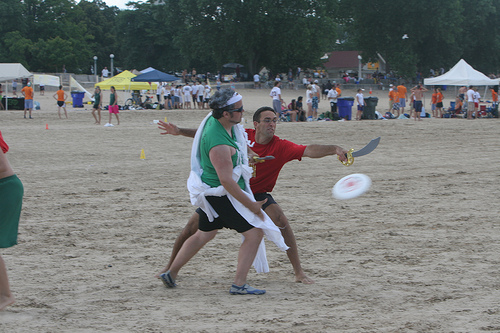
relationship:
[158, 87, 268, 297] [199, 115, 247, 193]
man in shirt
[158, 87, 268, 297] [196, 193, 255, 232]
man in shorts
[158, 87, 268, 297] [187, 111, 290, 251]
man wrapped in toilet paper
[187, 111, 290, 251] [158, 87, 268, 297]
toilet paper around man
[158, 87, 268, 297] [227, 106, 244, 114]
man wearing glasses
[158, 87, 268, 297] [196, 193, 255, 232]
man wearing shorts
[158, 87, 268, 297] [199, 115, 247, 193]
man wearing shirt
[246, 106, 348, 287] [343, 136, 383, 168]
man holding knife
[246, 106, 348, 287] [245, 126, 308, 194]
man wearing shirt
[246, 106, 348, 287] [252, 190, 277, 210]
man in shorts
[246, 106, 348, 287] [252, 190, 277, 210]
man wearing shorts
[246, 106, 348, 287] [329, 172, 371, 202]
man playing frisbee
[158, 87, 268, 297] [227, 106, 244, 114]
man wearing sunglasses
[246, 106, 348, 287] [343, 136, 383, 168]
man has sword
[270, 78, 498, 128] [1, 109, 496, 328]
people on sand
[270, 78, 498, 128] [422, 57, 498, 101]
people near tent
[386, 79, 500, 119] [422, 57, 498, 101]
crowd near tent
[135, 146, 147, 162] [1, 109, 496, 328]
cone on sand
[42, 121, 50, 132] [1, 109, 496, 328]
cone in sand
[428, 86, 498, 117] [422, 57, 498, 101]
people under tent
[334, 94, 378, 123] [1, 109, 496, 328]
trash cans on sand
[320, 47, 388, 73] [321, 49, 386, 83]
roof of building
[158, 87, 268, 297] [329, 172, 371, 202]
man threw frisbee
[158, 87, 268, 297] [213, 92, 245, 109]
man wearing headband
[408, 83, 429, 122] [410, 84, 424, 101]
person not wearing shirt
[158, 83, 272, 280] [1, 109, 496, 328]
toilet paper on beach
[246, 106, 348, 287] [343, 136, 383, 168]
guy weilding sword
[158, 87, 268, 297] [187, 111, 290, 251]
guy wearing toga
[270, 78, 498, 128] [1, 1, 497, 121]
people in background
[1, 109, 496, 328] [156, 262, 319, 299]
sand beneath feet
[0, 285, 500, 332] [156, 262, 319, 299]
area beneath feet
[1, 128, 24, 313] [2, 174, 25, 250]
person wearing shorts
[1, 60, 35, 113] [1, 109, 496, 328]
structure on beach